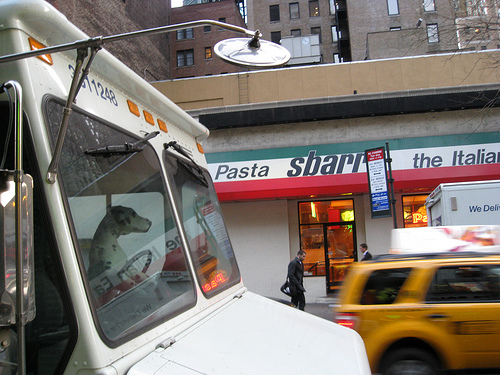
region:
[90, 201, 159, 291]
the dog is white with black spots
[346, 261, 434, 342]
the car is yellow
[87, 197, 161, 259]
the dog is sitting in the driver seat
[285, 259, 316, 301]
the coat is black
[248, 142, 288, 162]
this line is green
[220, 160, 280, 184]
this line is white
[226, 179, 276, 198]
this line is red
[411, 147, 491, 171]
the words are black in color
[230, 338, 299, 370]
this van is white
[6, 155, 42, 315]
the mirror is silver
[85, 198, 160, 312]
a dalmation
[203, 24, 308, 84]
a mirror over the hood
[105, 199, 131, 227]
the ear of the dalmation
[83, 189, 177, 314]
a dog on the dashboard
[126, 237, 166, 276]
the steering wheel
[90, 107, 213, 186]
a set of windshield wipers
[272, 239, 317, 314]
a man on the sidewalk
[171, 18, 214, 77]
windows on the building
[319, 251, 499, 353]
yellow suv driving by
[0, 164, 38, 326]
the back of the sideview mirror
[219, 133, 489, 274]
sbarro Italian restaurant banner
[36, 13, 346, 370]
White delivery truck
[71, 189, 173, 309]
Dalmation in driver's seat of white truck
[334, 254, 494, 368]
Yellow cab on road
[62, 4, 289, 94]
Rear view mirror on truck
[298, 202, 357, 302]
Door for restaurant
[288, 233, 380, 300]
Two men by restaurant door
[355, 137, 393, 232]
Sign on pole for bus stop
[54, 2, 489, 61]
Apartment buildings above restaurant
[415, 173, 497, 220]
Another delivery truck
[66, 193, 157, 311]
black and white dog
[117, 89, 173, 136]
yellow reflectors on truck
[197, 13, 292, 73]
circular mirror on pole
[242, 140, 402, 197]
words on building awning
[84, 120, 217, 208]
wipers on top of windshield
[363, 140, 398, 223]
rectangle sign on pole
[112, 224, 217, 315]
reflection on truck windshield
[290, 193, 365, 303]
windows on top and side of door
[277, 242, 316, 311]
man walking in front of building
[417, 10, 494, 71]
tree branches with no leaves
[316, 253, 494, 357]
yellow taxi on road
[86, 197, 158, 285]
dog in driver's seat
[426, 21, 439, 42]
window on front of building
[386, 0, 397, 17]
window on front of building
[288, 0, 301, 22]
window on front of building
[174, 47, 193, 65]
window on front of building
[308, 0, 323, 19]
window on front of building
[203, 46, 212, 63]
window on front of building